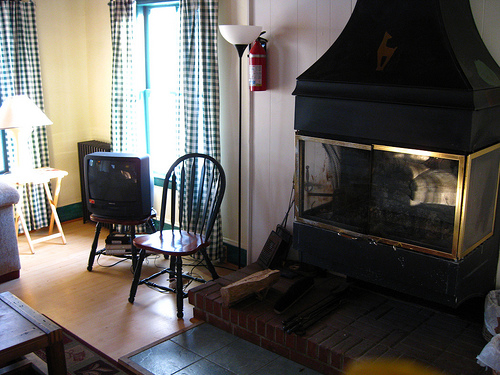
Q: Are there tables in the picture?
A: Yes, there is a table.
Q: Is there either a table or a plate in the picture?
A: Yes, there is a table.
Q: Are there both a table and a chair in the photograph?
A: Yes, there are both a table and a chair.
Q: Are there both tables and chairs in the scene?
A: Yes, there are both a table and a chair.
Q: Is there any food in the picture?
A: No, there is no food.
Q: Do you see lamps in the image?
A: Yes, there is a lamp.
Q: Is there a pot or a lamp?
A: Yes, there is a lamp.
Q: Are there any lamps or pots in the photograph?
A: Yes, there is a lamp.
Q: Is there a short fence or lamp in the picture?
A: Yes, there is a short lamp.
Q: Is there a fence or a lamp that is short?
A: Yes, the lamp is short.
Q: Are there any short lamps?
A: Yes, there is a short lamp.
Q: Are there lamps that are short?
A: Yes, there is a lamp that is short.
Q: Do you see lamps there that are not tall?
A: Yes, there is a short lamp.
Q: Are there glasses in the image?
A: No, there are no glasses.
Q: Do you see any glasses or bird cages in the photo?
A: No, there are no glasses or bird cages.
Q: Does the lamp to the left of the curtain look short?
A: Yes, the lamp is short.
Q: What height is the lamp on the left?
A: The lamp is short.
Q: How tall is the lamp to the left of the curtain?
A: The lamp is short.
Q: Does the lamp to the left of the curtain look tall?
A: No, the lamp is short.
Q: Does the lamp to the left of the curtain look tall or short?
A: The lamp is short.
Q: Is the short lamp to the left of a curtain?
A: Yes, the lamp is to the left of a curtain.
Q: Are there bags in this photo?
A: No, there are no bags.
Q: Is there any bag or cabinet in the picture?
A: No, there are no bags or cabinets.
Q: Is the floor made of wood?
A: Yes, the floor is made of wood.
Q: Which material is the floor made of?
A: The floor is made of wood.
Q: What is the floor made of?
A: The floor is made of wood.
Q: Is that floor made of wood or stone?
A: The floor is made of wood.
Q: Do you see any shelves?
A: No, there are no shelves.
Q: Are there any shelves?
A: No, there are no shelves.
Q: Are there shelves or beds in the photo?
A: No, there are no shelves or beds.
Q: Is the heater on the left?
A: Yes, the heater is on the left of the image.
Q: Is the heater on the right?
A: No, the heater is on the left of the image.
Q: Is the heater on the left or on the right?
A: The heater is on the left of the image.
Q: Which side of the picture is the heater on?
A: The heater is on the left of the image.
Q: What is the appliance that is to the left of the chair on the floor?
A: The appliance is a heater.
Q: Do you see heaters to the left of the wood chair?
A: Yes, there is a heater to the left of the chair.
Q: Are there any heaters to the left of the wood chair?
A: Yes, there is a heater to the left of the chair.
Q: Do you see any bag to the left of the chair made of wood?
A: No, there is a heater to the left of the chair.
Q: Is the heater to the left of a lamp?
A: Yes, the heater is to the left of a lamp.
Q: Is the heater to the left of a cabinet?
A: No, the heater is to the left of a lamp.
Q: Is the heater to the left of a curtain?
A: Yes, the heater is to the left of a curtain.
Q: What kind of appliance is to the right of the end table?
A: The appliance is a heater.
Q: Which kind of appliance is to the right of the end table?
A: The appliance is a heater.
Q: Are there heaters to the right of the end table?
A: Yes, there is a heater to the right of the end table.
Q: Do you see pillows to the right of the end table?
A: No, there is a heater to the right of the end table.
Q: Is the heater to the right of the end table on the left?
A: Yes, the heater is to the right of the end table.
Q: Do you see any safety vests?
A: No, there are no safety vests.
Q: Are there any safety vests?
A: No, there are no safety vests.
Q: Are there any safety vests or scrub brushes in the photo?
A: No, there are no safety vests or scrub brushes.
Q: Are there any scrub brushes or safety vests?
A: No, there are no safety vests or scrub brushes.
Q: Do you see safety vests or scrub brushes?
A: No, there are no safety vests or scrub brushes.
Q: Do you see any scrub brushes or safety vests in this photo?
A: No, there are no safety vests or scrub brushes.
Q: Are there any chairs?
A: Yes, there is a chair.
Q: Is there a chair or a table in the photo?
A: Yes, there is a chair.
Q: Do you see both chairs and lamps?
A: Yes, there are both a chair and a lamp.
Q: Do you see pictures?
A: No, there are no pictures.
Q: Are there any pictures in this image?
A: No, there are no pictures.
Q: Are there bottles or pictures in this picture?
A: No, there are no pictures or bottles.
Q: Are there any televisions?
A: Yes, there is a television.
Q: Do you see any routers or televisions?
A: Yes, there is a television.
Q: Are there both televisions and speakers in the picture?
A: No, there is a television but no speakers.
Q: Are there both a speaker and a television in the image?
A: No, there is a television but no speakers.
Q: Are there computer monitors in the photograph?
A: No, there are no computer monitors.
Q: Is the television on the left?
A: Yes, the television is on the left of the image.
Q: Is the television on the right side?
A: No, the television is on the left of the image.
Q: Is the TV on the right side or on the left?
A: The TV is on the left of the image.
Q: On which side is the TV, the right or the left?
A: The TV is on the left of the image.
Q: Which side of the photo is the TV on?
A: The TV is on the left of the image.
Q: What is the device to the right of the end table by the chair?
A: The device is a television.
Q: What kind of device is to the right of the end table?
A: The device is a television.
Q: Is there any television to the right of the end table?
A: Yes, there is a television to the right of the end table.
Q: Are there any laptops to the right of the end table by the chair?
A: No, there is a television to the right of the end table.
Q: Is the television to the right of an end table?
A: Yes, the television is to the right of an end table.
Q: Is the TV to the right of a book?
A: No, the TV is to the right of an end table.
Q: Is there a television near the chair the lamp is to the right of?
A: Yes, there is a television near the chair.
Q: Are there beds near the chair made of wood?
A: No, there is a television near the chair.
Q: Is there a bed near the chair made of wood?
A: No, there is a television near the chair.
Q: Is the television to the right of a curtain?
A: No, the television is to the left of a curtain.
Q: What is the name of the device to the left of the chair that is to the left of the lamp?
A: The device is a television.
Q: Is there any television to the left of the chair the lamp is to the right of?
A: Yes, there is a television to the left of the chair.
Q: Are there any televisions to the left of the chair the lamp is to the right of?
A: Yes, there is a television to the left of the chair.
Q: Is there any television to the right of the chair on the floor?
A: No, the television is to the left of the chair.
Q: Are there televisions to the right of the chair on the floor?
A: No, the television is to the left of the chair.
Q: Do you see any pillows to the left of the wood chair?
A: No, there is a television to the left of the chair.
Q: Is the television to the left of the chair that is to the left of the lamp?
A: Yes, the television is to the left of the chair.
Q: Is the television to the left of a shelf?
A: No, the television is to the left of the chair.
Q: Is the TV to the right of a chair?
A: No, the TV is to the left of a chair.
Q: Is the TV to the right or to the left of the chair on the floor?
A: The TV is to the left of the chair.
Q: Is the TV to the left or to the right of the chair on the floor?
A: The TV is to the left of the chair.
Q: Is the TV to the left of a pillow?
A: No, the TV is to the left of the lamp.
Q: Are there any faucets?
A: No, there are no faucets.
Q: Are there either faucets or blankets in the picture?
A: No, there are no faucets or blankets.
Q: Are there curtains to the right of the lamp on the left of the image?
A: Yes, there is a curtain to the right of the lamp.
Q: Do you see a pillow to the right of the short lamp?
A: No, there is a curtain to the right of the lamp.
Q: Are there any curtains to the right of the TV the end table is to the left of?
A: Yes, there is a curtain to the right of the TV.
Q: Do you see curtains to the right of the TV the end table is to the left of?
A: Yes, there is a curtain to the right of the TV.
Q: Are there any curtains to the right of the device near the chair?
A: Yes, there is a curtain to the right of the TV.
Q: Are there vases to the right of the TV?
A: No, there is a curtain to the right of the TV.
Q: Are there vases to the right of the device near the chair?
A: No, there is a curtain to the right of the TV.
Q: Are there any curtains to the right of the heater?
A: Yes, there is a curtain to the right of the heater.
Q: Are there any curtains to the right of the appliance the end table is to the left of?
A: Yes, there is a curtain to the right of the heater.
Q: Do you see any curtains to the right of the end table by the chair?
A: Yes, there is a curtain to the right of the end table.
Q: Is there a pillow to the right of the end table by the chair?
A: No, there is a curtain to the right of the end table.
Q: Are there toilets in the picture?
A: No, there are no toilets.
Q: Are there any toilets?
A: No, there are no toilets.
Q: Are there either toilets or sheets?
A: No, there are no toilets or sheets.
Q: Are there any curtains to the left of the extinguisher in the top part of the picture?
A: Yes, there is a curtain to the left of the extinguisher.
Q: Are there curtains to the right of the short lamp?
A: Yes, there is a curtain to the right of the lamp.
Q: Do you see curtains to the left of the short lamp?
A: No, the curtain is to the right of the lamp.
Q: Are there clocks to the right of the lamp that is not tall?
A: No, there is a curtain to the right of the lamp.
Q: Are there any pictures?
A: No, there are no pictures.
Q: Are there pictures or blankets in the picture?
A: No, there are no pictures or blankets.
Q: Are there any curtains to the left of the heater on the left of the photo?
A: Yes, there is a curtain to the left of the heater.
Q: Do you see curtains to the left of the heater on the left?
A: Yes, there is a curtain to the left of the heater.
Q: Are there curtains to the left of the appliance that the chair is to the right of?
A: Yes, there is a curtain to the left of the heater.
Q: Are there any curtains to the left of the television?
A: Yes, there is a curtain to the left of the television.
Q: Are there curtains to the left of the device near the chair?
A: Yes, there is a curtain to the left of the television.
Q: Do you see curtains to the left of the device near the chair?
A: Yes, there is a curtain to the left of the television.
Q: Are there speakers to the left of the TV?
A: No, there is a curtain to the left of the TV.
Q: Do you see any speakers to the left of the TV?
A: No, there is a curtain to the left of the TV.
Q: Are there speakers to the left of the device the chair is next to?
A: No, there is a curtain to the left of the TV.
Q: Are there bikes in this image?
A: No, there are no bikes.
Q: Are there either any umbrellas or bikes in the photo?
A: No, there are no bikes or umbrellas.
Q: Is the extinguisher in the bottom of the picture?
A: No, the extinguisher is in the top of the image.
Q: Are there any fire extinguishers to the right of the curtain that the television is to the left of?
A: Yes, there is a fire extinguisher to the right of the curtain.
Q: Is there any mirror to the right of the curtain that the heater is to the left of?
A: No, there is a fire extinguisher to the right of the curtain.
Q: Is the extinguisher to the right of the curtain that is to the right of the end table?
A: Yes, the extinguisher is to the right of the curtain.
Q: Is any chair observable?
A: Yes, there is a chair.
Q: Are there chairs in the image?
A: Yes, there is a chair.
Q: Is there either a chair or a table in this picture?
A: Yes, there is a chair.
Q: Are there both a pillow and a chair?
A: No, there is a chair but no pillows.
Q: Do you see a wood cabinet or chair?
A: Yes, there is a wood chair.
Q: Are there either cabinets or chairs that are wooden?
A: Yes, the chair is wooden.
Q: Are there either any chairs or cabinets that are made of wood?
A: Yes, the chair is made of wood.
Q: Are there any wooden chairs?
A: Yes, there is a wood chair.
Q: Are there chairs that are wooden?
A: Yes, there is a chair that is wooden.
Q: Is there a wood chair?
A: Yes, there is a chair that is made of wood.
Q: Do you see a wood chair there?
A: Yes, there is a chair that is made of wood.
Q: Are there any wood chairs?
A: Yes, there is a chair that is made of wood.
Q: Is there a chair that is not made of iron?
A: Yes, there is a chair that is made of wood.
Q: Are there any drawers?
A: No, there are no drawers.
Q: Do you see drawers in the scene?
A: No, there are no drawers.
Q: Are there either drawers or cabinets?
A: No, there are no drawers or cabinets.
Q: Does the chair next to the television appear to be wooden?
A: Yes, the chair is wooden.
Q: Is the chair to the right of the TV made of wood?
A: Yes, the chair is made of wood.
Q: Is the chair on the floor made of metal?
A: No, the chair is made of wood.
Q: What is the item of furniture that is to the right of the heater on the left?
A: The piece of furniture is a chair.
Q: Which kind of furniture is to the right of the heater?
A: The piece of furniture is a chair.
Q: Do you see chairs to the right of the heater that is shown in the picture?
A: Yes, there is a chair to the right of the heater.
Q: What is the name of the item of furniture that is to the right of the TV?
A: The piece of furniture is a chair.